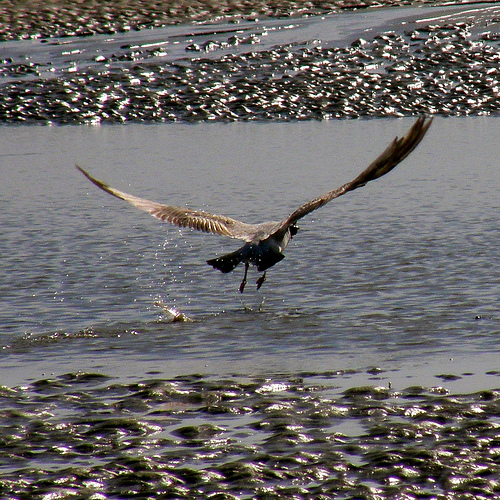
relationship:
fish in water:
[170, 313, 191, 325] [4, 120, 499, 345]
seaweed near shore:
[9, 369, 492, 498] [17, 324, 490, 498]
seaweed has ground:
[9, 369, 492, 498] [0, 0, 499, 498]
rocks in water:
[145, 61, 300, 126] [14, 300, 498, 462]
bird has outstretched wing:
[75, 115, 435, 294] [75, 162, 254, 244]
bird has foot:
[75, 115, 435, 294] [252, 269, 267, 289]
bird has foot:
[75, 115, 435, 294] [235, 277, 244, 294]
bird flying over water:
[34, 97, 492, 324] [0, 121, 499, 383]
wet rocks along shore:
[253, 64, 328, 106] [3, 4, 499, 124]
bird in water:
[75, 115, 435, 294] [0, 121, 499, 383]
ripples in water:
[0, 307, 336, 357] [0, 121, 499, 383]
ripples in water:
[0, 307, 336, 357] [286, 117, 369, 166]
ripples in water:
[0, 299, 336, 356] [0, 121, 499, 383]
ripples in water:
[227, 158, 297, 196] [0, 121, 499, 383]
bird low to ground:
[75, 115, 435, 294] [0, 0, 499, 498]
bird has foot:
[75, 115, 435, 294] [255, 263, 266, 292]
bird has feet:
[75, 115, 435, 294] [239, 279, 247, 294]